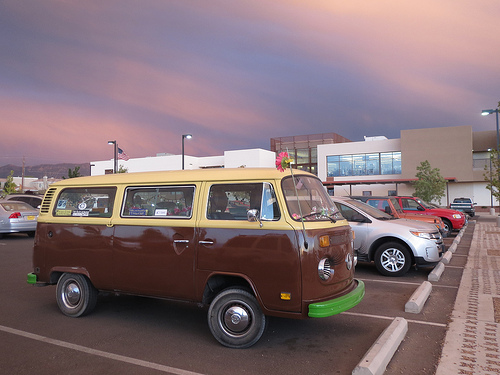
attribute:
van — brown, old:
[27, 147, 366, 348]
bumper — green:
[308, 277, 365, 318]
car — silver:
[265, 194, 445, 276]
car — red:
[367, 194, 465, 236]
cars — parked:
[1, 145, 478, 349]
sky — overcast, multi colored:
[1, 0, 500, 166]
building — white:
[89, 124, 500, 212]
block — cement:
[352, 317, 409, 374]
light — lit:
[185, 135, 193, 141]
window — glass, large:
[326, 151, 403, 178]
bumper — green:
[27, 268, 39, 285]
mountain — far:
[1, 162, 91, 180]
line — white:
[1, 324, 206, 374]